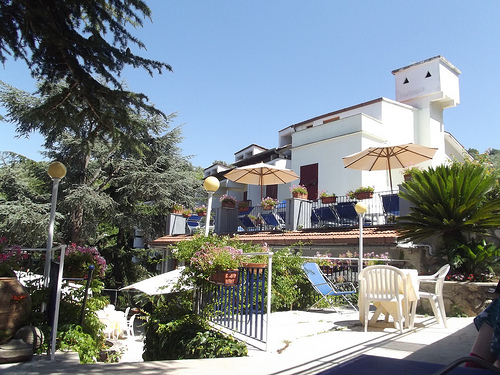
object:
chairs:
[407, 264, 454, 328]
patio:
[226, 271, 444, 355]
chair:
[359, 265, 419, 334]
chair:
[300, 260, 359, 311]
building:
[275, 55, 495, 229]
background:
[0, 3, 499, 223]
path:
[2, 344, 245, 374]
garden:
[7, 252, 492, 355]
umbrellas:
[225, 162, 305, 187]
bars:
[199, 267, 266, 349]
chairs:
[263, 208, 290, 233]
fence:
[236, 190, 396, 230]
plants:
[187, 218, 310, 321]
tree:
[0, 0, 150, 131]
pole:
[353, 215, 366, 276]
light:
[203, 175, 220, 192]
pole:
[203, 193, 218, 232]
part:
[387, 54, 464, 109]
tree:
[397, 163, 499, 264]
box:
[209, 267, 240, 284]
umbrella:
[340, 137, 437, 172]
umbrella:
[224, 160, 299, 189]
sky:
[142, 11, 385, 91]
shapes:
[401, 76, 413, 85]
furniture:
[298, 243, 461, 336]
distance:
[10, 7, 171, 301]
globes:
[355, 198, 369, 213]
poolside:
[133, 149, 413, 333]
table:
[345, 267, 420, 285]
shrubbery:
[178, 236, 317, 300]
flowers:
[202, 243, 221, 257]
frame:
[300, 248, 355, 299]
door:
[300, 165, 319, 210]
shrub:
[147, 291, 210, 349]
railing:
[188, 264, 355, 312]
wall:
[407, 283, 496, 317]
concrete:
[210, 286, 451, 363]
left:
[5, 7, 124, 261]